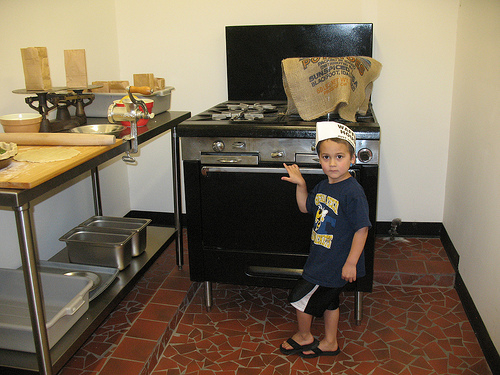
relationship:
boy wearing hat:
[277, 120, 373, 360] [314, 117, 356, 147]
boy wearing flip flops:
[277, 120, 373, 360] [275, 332, 342, 359]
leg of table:
[89, 165, 104, 220] [1, 112, 190, 374]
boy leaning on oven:
[277, 120, 373, 360] [172, 15, 387, 327]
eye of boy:
[322, 152, 331, 161] [277, 120, 373, 360]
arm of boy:
[339, 188, 376, 284] [277, 120, 373, 360]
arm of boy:
[278, 162, 329, 214] [277, 120, 373, 360]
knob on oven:
[209, 139, 226, 154] [172, 15, 387, 327]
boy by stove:
[277, 120, 373, 360] [170, 30, 433, 335]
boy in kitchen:
[277, 120, 373, 360] [0, 6, 496, 373]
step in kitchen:
[117, 277, 194, 355] [0, 6, 496, 373]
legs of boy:
[279, 282, 341, 359] [277, 120, 373, 360]